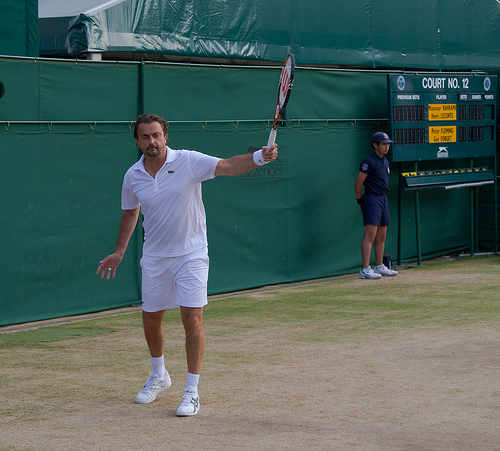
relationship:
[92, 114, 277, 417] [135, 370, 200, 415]
man wearing shoes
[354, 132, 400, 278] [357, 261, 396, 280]
man wearing shoes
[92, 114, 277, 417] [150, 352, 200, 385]
man wearing socks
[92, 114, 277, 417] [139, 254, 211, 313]
man wearing shorts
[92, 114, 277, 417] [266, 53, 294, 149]
man holding racket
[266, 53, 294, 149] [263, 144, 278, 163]
racket in left hand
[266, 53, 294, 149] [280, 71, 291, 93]
racket has a w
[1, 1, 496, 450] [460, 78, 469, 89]
court number 12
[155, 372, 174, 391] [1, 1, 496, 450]
heel off court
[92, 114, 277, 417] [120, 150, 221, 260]
man wearing a shirt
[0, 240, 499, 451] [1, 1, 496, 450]
grass on court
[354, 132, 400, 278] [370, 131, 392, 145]
man wearing a hat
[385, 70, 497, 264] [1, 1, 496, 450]
score board on court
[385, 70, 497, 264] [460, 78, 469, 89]
score board for court 12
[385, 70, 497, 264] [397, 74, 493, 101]
score board has lettering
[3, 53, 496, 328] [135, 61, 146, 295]
fence has a pole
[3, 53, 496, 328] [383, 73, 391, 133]
fence has a pole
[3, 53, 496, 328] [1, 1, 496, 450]
fence on court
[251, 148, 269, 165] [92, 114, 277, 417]
wristband on man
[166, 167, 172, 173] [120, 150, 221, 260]
logo on shirt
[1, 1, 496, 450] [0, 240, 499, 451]
court has grass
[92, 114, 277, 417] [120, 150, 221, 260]
man wearing shirt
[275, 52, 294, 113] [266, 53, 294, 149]
head on racket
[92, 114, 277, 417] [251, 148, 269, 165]
man wearing wristband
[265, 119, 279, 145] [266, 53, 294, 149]
handle on racket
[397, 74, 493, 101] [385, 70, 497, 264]
lettering on score board